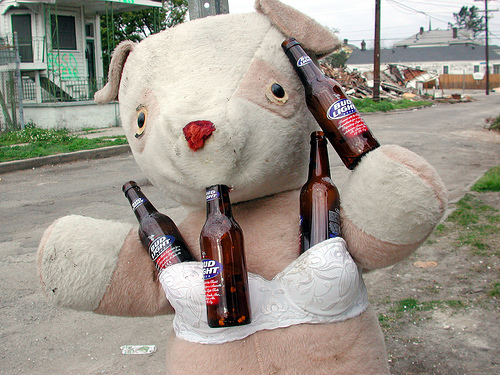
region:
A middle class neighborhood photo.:
[1, 0, 498, 373]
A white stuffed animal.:
[33, 0, 449, 372]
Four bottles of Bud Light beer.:
[123, 38, 385, 345]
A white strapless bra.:
[158, 238, 381, 345]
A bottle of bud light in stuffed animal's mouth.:
[197, 183, 252, 334]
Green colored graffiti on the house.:
[41, 23, 86, 83]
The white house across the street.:
[0, 0, 97, 134]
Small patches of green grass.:
[391, 302, 499, 312]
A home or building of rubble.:
[321, 36, 462, 98]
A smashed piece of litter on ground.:
[117, 343, 162, 355]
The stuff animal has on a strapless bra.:
[130, 246, 407, 357]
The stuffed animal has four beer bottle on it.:
[90, 30, 430, 310]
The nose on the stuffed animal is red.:
[170, 107, 221, 152]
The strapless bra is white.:
[146, 260, 387, 343]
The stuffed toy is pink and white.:
[82, 28, 457, 373]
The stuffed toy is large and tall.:
[70, 13, 440, 326]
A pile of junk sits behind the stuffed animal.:
[346, 64, 471, 102]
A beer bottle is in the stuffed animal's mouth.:
[191, 169, 286, 330]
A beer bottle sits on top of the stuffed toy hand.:
[276, 40, 395, 164]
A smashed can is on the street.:
[109, 326, 177, 366]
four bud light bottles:
[101, 38, 382, 335]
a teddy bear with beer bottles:
[47, 1, 450, 373]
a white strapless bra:
[148, 230, 385, 345]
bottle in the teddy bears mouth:
[186, 155, 260, 335]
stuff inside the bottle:
[203, 275, 252, 331]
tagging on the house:
[39, 40, 87, 89]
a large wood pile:
[328, 56, 432, 107]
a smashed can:
[116, 342, 158, 361]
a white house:
[5, 0, 162, 145]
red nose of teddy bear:
[172, 113, 222, 153]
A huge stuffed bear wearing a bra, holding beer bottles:
[36, 0, 440, 374]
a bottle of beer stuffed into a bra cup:
[119, 180, 195, 269]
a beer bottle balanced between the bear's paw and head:
[282, 38, 378, 163]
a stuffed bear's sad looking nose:
[180, 119, 215, 153]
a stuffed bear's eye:
[266, 81, 291, 107]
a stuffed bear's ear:
[90, 37, 141, 107]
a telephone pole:
[470, 1, 498, 95]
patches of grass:
[403, 166, 498, 344]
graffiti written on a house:
[46, 49, 85, 83]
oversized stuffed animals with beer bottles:
[20, 9, 480, 372]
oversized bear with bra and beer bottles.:
[62, 17, 439, 362]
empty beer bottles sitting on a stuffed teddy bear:
[105, 24, 410, 360]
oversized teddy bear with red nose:
[76, 30, 418, 338]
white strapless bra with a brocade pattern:
[128, 187, 409, 356]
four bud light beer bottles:
[90, 9, 411, 352]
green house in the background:
[13, 0, 483, 370]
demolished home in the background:
[311, 28, 474, 140]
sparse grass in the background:
[316, 142, 489, 368]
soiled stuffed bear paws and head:
[42, 15, 465, 356]